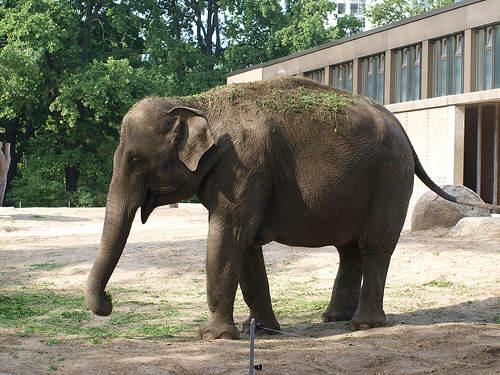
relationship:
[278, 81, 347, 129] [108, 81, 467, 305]
grass on elephant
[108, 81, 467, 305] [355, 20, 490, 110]
elephant near building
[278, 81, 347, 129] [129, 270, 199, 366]
grass in dirt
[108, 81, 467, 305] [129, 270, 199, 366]
elephant in dirt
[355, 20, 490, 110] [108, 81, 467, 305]
building behind elephant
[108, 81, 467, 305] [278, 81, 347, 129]
elephant has grass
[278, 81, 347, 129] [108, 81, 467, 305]
grass near elephant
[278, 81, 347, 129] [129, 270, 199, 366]
grass on dirt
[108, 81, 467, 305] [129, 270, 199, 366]
elephant on dirt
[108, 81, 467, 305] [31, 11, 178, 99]
elephant near trees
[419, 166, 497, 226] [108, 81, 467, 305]
tail on elephant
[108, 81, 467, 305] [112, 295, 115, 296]
elephant eating hay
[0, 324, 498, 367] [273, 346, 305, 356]
mound of hay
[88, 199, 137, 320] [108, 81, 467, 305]
trunk on elephant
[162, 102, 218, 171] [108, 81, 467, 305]
ear on elephant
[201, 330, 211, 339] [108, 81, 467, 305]
toe nail on elephant